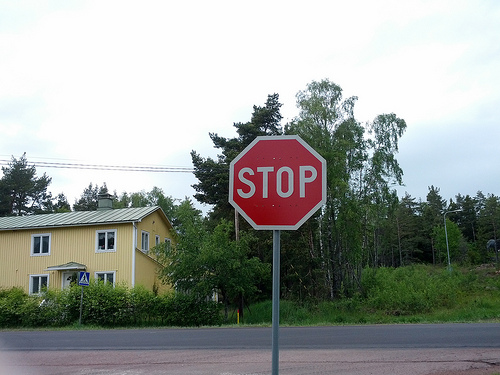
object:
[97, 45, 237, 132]
clouds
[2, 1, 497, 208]
sky